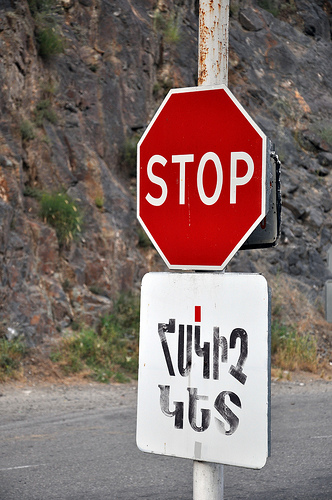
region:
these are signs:
[85, 57, 227, 390]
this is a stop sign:
[135, 152, 211, 250]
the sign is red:
[129, 88, 272, 274]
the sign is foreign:
[141, 298, 235, 412]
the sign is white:
[133, 299, 245, 430]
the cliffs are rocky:
[36, 132, 124, 230]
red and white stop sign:
[133, 68, 280, 268]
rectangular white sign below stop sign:
[134, 268, 268, 466]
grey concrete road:
[6, 382, 326, 496]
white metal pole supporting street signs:
[186, 467, 230, 497]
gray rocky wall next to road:
[6, 3, 329, 341]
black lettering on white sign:
[149, 310, 259, 430]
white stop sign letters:
[144, 148, 258, 209]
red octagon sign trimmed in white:
[129, 80, 268, 266]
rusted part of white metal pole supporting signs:
[193, 3, 230, 95]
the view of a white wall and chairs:
[186, 466, 198, 489]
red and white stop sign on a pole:
[104, 131, 279, 269]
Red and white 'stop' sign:
[136, 84, 267, 273]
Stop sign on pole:
[135, 83, 266, 271]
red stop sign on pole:
[135, 86, 267, 269]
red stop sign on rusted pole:
[133, 77, 259, 272]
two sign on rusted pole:
[125, 79, 270, 465]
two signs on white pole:
[132, 76, 275, 473]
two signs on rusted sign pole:
[133, 80, 276, 474]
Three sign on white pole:
[131, 79, 298, 470]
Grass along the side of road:
[54, 293, 130, 381]